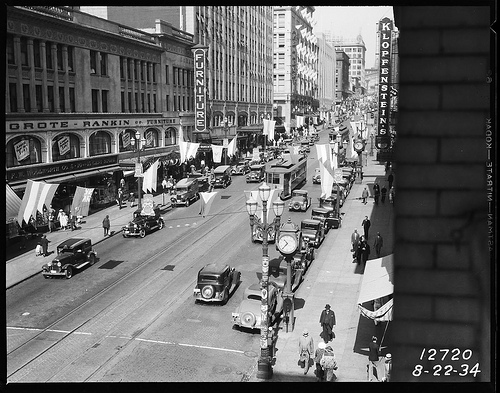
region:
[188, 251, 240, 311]
a vehicle on the road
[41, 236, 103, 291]
a vehicle on the road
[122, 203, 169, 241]
a vehicle on the road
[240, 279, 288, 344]
a vehicle on the road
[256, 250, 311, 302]
a vehicle on the road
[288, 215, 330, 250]
a vehicle on the road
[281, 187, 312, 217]
a vehicle on the road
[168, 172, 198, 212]
a vehicle on the road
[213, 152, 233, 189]
a vehicle on the road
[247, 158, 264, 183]
a vehicle on the road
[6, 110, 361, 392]
The street in the photo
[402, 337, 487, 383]
The date in the photo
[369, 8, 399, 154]
The sign on the building on the right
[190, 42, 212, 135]
The sign on the building on the left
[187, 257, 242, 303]
The black car driving away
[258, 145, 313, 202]
The trolley in the street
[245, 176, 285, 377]
The lamp post nearest the camera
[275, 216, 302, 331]
The clock nearest the camera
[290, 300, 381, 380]
The people next to the date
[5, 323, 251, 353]
The white line across the street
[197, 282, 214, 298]
a spare tire on a car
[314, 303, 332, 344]
a man wearing a dark suit and hat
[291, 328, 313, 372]
a man walking down the sidewalk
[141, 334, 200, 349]
a white line in the street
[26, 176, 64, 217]
a flags hanging outside a business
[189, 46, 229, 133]
a large business sign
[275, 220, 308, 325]
a clock on a tall pole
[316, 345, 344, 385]
two women passing a man on the sidewalk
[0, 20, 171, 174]
a large department store building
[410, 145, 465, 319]
bricks in the wall of a building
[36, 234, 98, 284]
a car on the street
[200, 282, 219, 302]
a spare tire on the car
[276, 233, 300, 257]
a round clock on a pole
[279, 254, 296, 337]
a metal clock pole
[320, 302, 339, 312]
a hat on a man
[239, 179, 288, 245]
three street lamps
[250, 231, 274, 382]
a metal lamp post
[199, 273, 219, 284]
a rear car window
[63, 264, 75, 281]
a front car wheel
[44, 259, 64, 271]
a pair of head lights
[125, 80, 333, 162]
flags flying along the street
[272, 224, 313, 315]
a street clock on the sidewalk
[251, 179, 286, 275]
street light has three globes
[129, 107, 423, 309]
the picture is in black and white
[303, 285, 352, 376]
people walking on the sidewalk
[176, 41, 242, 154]
the building is a furniture store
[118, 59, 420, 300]
a major road in the city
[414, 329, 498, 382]
taken on 8-22-34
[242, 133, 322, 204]
trolley in the road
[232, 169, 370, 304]
cars parked along the street